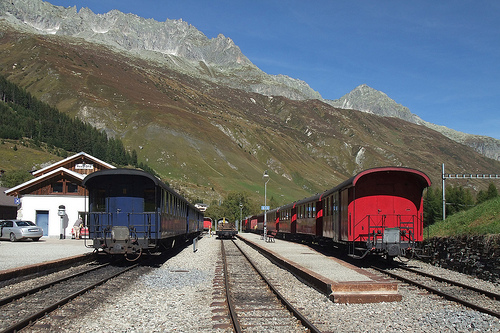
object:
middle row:
[220, 234, 316, 333]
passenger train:
[239, 165, 435, 263]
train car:
[256, 207, 279, 237]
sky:
[47, 2, 500, 138]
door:
[34, 210, 49, 235]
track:
[211, 237, 321, 331]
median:
[235, 232, 402, 303]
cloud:
[54, 0, 500, 136]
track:
[381, 255, 498, 317]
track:
[11, 258, 131, 331]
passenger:
[243, 212, 259, 226]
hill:
[2, 29, 500, 203]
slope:
[2, 27, 495, 171]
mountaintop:
[332, 84, 407, 115]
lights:
[442, 163, 500, 221]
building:
[3, 167, 94, 239]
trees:
[0, 100, 35, 142]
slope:
[0, 128, 73, 163]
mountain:
[0, 0, 500, 156]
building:
[30, 151, 118, 178]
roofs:
[3, 167, 90, 196]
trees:
[70, 122, 135, 164]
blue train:
[78, 165, 206, 265]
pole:
[262, 175, 270, 243]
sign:
[260, 205, 269, 210]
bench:
[266, 229, 277, 242]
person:
[73, 217, 84, 240]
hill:
[417, 192, 500, 240]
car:
[0, 218, 44, 242]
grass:
[425, 194, 500, 237]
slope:
[404, 187, 499, 257]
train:
[216, 216, 238, 238]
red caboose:
[321, 166, 433, 265]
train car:
[293, 195, 322, 246]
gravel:
[150, 277, 221, 318]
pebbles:
[87, 313, 131, 333]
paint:
[105, 195, 144, 233]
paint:
[356, 188, 413, 224]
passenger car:
[242, 215, 258, 232]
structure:
[435, 160, 497, 214]